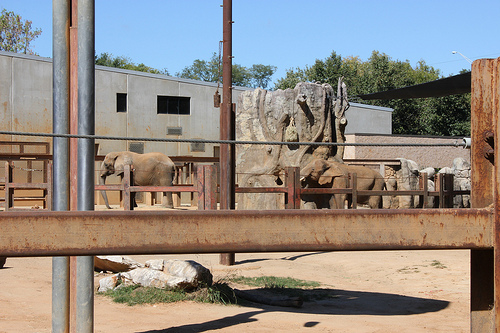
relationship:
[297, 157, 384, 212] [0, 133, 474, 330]
elephant inside a pen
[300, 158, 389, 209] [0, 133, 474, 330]
elephant inside a pen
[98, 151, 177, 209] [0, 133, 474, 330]
elephant inside a pen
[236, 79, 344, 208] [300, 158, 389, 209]
rock in front of elephant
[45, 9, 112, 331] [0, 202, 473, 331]
metal pole in ground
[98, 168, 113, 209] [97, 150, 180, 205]
long trunk on elephant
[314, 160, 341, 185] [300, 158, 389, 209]
ear on elephant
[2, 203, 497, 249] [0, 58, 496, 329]
pole holding fence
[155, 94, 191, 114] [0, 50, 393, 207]
window on a big building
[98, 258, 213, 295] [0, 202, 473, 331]
rock on ground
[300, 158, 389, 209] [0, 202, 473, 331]
elephant on ground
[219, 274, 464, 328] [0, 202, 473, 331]
large shadow on ground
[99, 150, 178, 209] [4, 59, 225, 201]
elephant by wall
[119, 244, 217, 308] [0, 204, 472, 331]
large stone in dirt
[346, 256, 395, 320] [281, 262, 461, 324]
patches of dirt on ground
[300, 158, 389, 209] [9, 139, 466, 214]
elephant in pen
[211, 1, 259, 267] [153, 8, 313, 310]
brown metal pole in middle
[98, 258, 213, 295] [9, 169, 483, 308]
rock in pen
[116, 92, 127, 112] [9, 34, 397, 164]
window on a building on building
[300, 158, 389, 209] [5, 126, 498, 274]
elephant in secure enclosure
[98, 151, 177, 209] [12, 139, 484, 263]
elephant walking around enclosure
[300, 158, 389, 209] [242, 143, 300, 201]
elephant looking for food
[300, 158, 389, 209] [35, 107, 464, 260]
elephant are enjoying the sun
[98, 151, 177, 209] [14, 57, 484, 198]
elephant are in a zoo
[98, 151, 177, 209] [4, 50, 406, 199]
elephant are by big building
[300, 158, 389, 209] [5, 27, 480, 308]
elephant are out in daytime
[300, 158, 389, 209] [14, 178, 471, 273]
elephant behind fence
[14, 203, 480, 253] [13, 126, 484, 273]
bar on fence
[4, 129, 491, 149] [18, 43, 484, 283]
rounded silver pipes on fence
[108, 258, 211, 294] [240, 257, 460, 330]
rock on dirt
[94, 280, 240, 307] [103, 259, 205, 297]
grass near rock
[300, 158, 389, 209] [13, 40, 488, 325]
elephant in an enclosure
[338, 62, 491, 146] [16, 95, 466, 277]
shade cover over enclosure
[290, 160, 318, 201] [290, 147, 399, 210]
long trunk on elephant